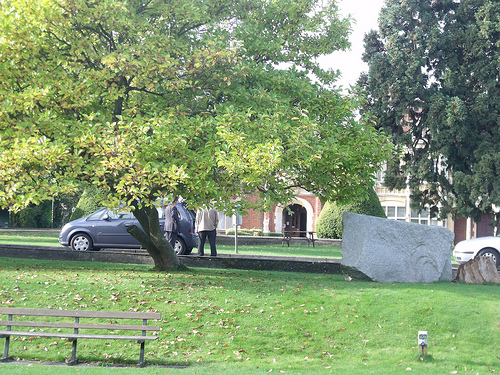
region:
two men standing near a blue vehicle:
[163, 196, 219, 256]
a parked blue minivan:
[59, 200, 199, 255]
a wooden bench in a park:
[1, 305, 162, 366]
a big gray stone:
[336, 211, 453, 284]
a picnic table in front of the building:
[279, 228, 319, 249]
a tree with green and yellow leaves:
[0, 0, 395, 272]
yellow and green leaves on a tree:
[1, 1, 397, 214]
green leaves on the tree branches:
[350, 14, 499, 221]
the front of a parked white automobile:
[452, 235, 498, 265]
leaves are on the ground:
[168, 269, 258, 354]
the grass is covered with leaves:
[210, 283, 266, 364]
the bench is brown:
[45, 281, 112, 356]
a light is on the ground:
[406, 323, 431, 368]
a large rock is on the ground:
[347, 200, 447, 320]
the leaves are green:
[90, 85, 255, 251]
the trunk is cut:
[107, 215, 244, 311]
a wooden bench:
[230, 215, 355, 296]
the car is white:
[451, 225, 468, 259]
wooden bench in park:
[12, 299, 166, 361]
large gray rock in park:
[332, 203, 472, 294]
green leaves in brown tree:
[221, 112, 293, 147]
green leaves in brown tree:
[282, 116, 339, 156]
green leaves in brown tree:
[390, 48, 431, 88]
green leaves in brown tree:
[412, 103, 443, 133]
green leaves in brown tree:
[404, 29, 434, 59]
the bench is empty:
[2, 290, 186, 356]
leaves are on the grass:
[155, 265, 303, 356]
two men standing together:
[145, 176, 231, 256]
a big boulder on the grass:
[320, 192, 462, 297]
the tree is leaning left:
[75, 131, 233, 293]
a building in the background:
[181, 132, 458, 239]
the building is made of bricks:
[232, 191, 268, 234]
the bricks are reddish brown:
[235, 185, 270, 232]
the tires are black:
[62, 227, 96, 252]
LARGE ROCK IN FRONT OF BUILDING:
[337, 205, 462, 282]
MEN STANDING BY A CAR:
[56, 190, 225, 265]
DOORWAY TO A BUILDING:
[269, 189, 317, 244]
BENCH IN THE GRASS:
[5, 309, 177, 369]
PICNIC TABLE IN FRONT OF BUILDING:
[277, 225, 322, 252]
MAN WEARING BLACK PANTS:
[191, 189, 224, 261]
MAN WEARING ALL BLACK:
[158, 195, 182, 255]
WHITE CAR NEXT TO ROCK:
[440, 213, 498, 275]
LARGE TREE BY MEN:
[27, 23, 242, 266]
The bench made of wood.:
[3, 298, 160, 368]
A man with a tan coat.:
[200, 198, 220, 250]